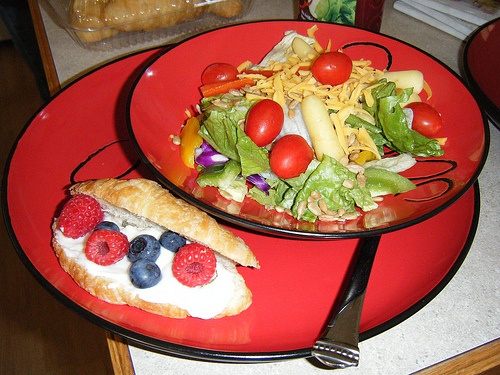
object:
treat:
[51, 177, 261, 320]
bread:
[50, 177, 260, 320]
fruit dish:
[456, 16, 500, 131]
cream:
[106, 268, 117, 276]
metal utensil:
[311, 234, 382, 369]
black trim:
[106, 320, 307, 364]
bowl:
[125, 19, 490, 242]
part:
[320, 333, 354, 360]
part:
[415, 239, 441, 270]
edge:
[193, 346, 267, 364]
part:
[269, 260, 309, 290]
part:
[253, 234, 271, 247]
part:
[274, 308, 287, 323]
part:
[345, 283, 360, 305]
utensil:
[189, 326, 293, 345]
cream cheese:
[121, 226, 141, 235]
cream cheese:
[61, 239, 76, 249]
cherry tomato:
[269, 134, 313, 179]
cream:
[164, 283, 209, 308]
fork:
[311, 235, 382, 369]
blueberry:
[126, 230, 187, 289]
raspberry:
[172, 243, 217, 287]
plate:
[0, 42, 481, 364]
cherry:
[94, 221, 120, 232]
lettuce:
[195, 110, 271, 190]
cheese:
[236, 24, 390, 160]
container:
[70, 0, 246, 43]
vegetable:
[170, 24, 448, 223]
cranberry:
[58, 192, 105, 240]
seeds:
[297, 164, 384, 222]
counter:
[27, 0, 500, 375]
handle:
[311, 235, 382, 369]